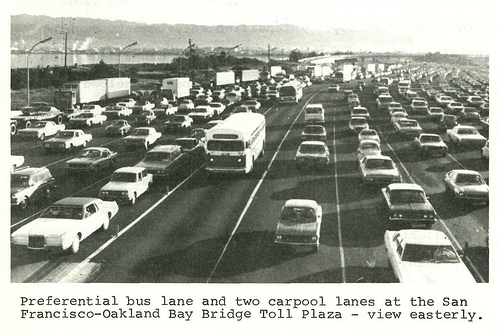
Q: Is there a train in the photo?
A: No, there are no trains.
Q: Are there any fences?
A: No, there are no fences.